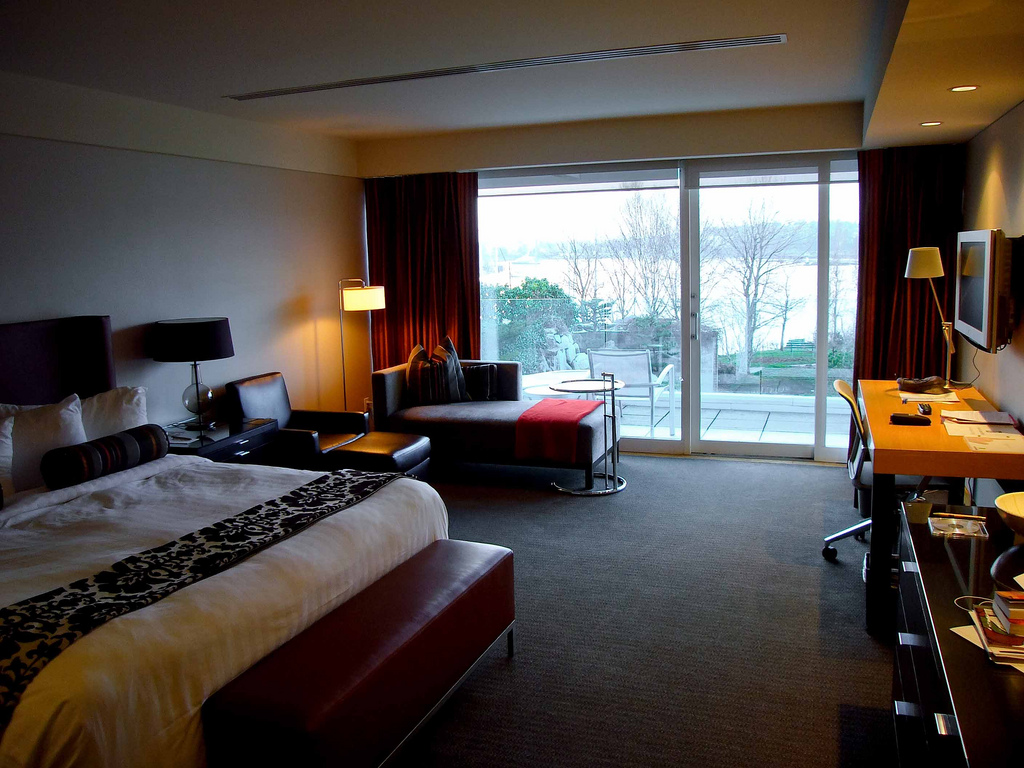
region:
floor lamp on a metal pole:
[330, 274, 389, 411]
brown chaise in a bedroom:
[370, 332, 621, 491]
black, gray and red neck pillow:
[32, 421, 172, 486]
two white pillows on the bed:
[13, 382, 160, 493]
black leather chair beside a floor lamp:
[223, 367, 433, 478]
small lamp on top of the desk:
[901, 246, 959, 398]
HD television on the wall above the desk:
[946, 224, 1022, 361]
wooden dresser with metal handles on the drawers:
[886, 495, 1022, 767]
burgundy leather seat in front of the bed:
[201, 537, 515, 766]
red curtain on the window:
[364, 181, 478, 276]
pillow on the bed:
[397, 337, 465, 414]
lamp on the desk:
[887, 230, 957, 385]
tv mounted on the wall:
[950, 222, 1012, 360]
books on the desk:
[964, 575, 1022, 659]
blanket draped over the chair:
[512, 395, 592, 454]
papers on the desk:
[939, 402, 1022, 450]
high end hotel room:
[3, 3, 1021, 762]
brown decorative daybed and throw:
[368, 341, 625, 491]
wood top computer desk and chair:
[819, 363, 1022, 638]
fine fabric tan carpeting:
[401, 442, 899, 766]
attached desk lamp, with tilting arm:
[898, 241, 959, 398]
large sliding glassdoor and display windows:
[468, 186, 860, 463]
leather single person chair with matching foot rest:
[222, 368, 429, 485]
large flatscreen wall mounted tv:
[945, 222, 1023, 353]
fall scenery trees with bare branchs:
[562, 188, 806, 394]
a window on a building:
[691, 141, 818, 467]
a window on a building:
[834, 177, 857, 446]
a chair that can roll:
[818, 363, 883, 578]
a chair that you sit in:
[227, 351, 383, 484]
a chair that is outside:
[589, 345, 672, 443]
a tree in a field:
[713, 209, 790, 378]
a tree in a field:
[561, 221, 619, 378]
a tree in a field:
[498, 279, 579, 378]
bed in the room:
[6, 351, 493, 740]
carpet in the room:
[546, 473, 787, 677]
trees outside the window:
[509, 192, 719, 361]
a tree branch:
[556, 237, 621, 349]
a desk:
[887, 424, 938, 457]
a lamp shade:
[341, 279, 387, 318]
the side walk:
[739, 401, 793, 444]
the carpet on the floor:
[629, 531, 738, 636]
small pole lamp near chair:
[332, 272, 387, 410]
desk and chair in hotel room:
[816, 368, 1020, 588]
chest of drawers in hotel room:
[871, 491, 1021, 764]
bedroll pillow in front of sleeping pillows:
[25, 418, 177, 496]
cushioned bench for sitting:
[196, 535, 529, 764]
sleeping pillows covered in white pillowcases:
[0, 384, 154, 482]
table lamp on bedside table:
[145, 307, 244, 438]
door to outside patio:
[679, 171, 825, 462]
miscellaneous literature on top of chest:
[917, 504, 1020, 681]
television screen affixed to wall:
[939, 224, 1019, 360]